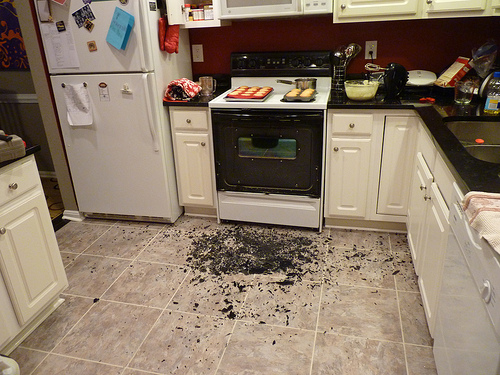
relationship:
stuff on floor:
[197, 229, 317, 275] [79, 287, 374, 363]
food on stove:
[227, 81, 320, 101] [224, 81, 329, 108]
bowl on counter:
[341, 74, 385, 99] [332, 76, 448, 116]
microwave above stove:
[210, 0, 343, 26] [224, 81, 329, 108]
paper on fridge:
[101, 4, 138, 57] [32, 1, 186, 223]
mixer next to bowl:
[367, 56, 412, 101] [341, 74, 385, 99]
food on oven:
[227, 81, 320, 101] [212, 110, 326, 201]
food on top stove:
[227, 81, 320, 101] [224, 81, 329, 108]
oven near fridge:
[212, 110, 326, 201] [32, 1, 186, 223]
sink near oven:
[436, 112, 498, 169] [212, 110, 326, 201]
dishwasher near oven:
[419, 175, 500, 374] [212, 110, 326, 201]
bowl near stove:
[341, 74, 385, 99] [224, 81, 329, 108]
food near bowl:
[227, 81, 320, 101] [341, 74, 385, 99]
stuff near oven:
[197, 229, 317, 275] [212, 110, 326, 201]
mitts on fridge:
[159, 10, 186, 57] [32, 1, 186, 223]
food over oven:
[227, 81, 320, 101] [212, 110, 326, 201]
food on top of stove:
[227, 81, 320, 101] [224, 81, 329, 108]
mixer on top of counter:
[367, 56, 412, 101] [332, 76, 448, 116]